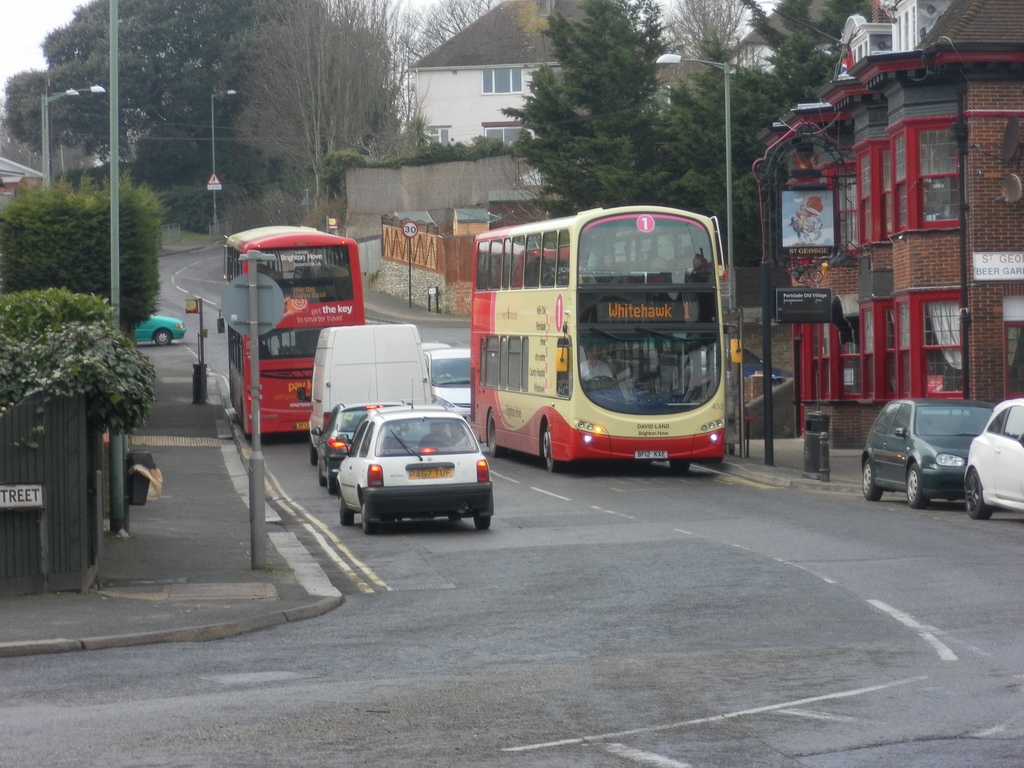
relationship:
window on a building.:
[911, 123, 965, 172] [781, 1, 1017, 442]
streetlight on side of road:
[103, 2, 122, 354] [6, 452, 977, 757]